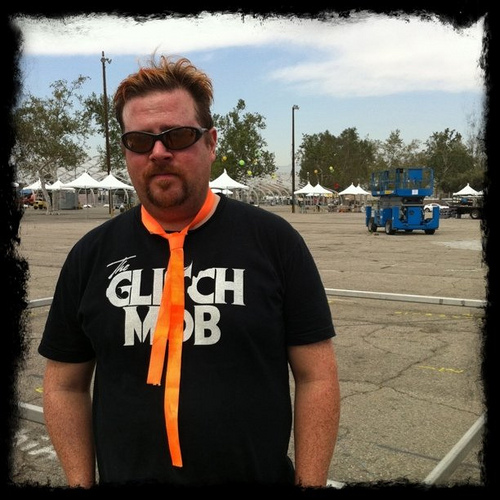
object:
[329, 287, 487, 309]
line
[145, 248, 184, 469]
tie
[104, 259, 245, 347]
text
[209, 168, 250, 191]
tent top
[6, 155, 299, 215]
building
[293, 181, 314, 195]
white tent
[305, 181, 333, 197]
umbrella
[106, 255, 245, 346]
lettering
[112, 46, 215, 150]
hair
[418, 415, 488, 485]
white line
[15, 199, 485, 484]
pavement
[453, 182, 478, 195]
white tent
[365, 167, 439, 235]
vehicle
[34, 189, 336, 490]
shirt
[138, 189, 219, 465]
ribbon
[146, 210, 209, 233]
neck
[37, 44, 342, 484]
man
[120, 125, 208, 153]
sunglasses